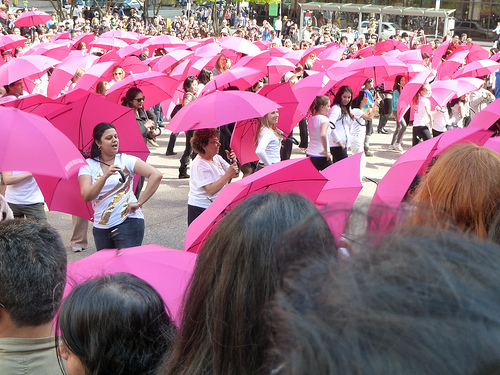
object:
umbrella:
[163, 80, 283, 134]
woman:
[78, 122, 163, 252]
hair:
[91, 122, 116, 158]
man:
[1, 208, 70, 375]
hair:
[0, 220, 67, 325]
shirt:
[77, 153, 144, 230]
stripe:
[93, 165, 129, 210]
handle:
[107, 163, 126, 183]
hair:
[410, 144, 499, 241]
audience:
[75, 15, 415, 44]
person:
[166, 191, 338, 375]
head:
[198, 191, 334, 281]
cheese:
[495, 0, 497, 6]